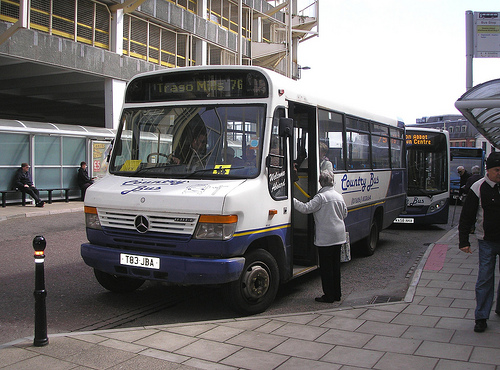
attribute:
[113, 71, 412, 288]
bus — white, blue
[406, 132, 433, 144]
sign — digital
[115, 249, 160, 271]
plate — white, black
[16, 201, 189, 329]
symbol — mercedes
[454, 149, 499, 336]
man — standing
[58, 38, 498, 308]
bus — standing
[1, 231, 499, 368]
sidewalk — grey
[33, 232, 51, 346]
pole — black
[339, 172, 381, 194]
letters — blue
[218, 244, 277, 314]
tire — black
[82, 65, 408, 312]
bus — staring